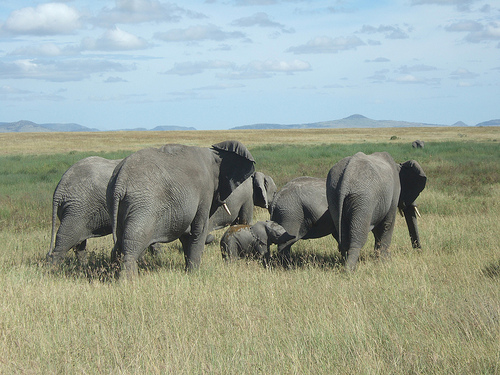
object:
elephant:
[47, 155, 122, 267]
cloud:
[8, 4, 76, 38]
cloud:
[94, 27, 152, 51]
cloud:
[14, 50, 127, 84]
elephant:
[390, 136, 397, 140]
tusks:
[222, 203, 231, 215]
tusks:
[414, 206, 422, 218]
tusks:
[222, 204, 232, 215]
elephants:
[270, 175, 325, 260]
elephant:
[220, 221, 293, 263]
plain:
[0, 126, 499, 374]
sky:
[0, 0, 499, 132]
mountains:
[0, 113, 500, 133]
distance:
[0, 0, 500, 129]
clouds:
[0, 0, 499, 104]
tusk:
[224, 201, 232, 216]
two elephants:
[388, 135, 425, 150]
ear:
[211, 139, 257, 200]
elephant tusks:
[222, 203, 232, 215]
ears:
[399, 160, 428, 208]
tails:
[47, 172, 124, 257]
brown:
[227, 225, 246, 233]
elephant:
[105, 140, 256, 279]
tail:
[110, 175, 128, 243]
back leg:
[119, 213, 153, 279]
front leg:
[183, 208, 210, 274]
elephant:
[328, 151, 427, 274]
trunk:
[413, 206, 422, 218]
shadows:
[63, 253, 117, 277]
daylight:
[0, 0, 500, 374]